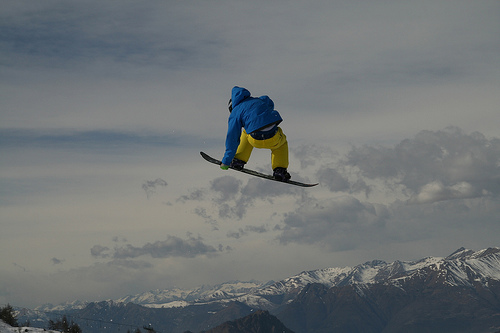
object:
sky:
[0, 0, 499, 308]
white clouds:
[0, 0, 499, 126]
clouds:
[50, 257, 63, 264]